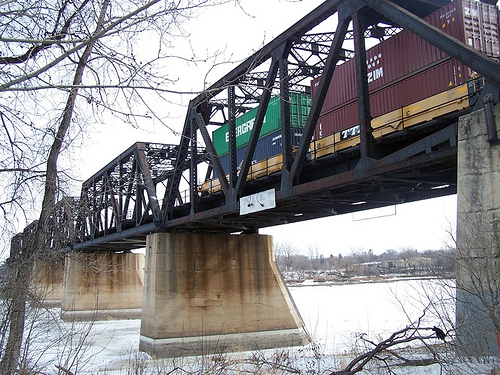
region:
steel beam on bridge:
[92, 181, 112, 248]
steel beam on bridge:
[100, 163, 122, 234]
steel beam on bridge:
[135, 145, 163, 223]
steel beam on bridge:
[160, 111, 190, 208]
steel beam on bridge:
[194, 109, 246, 210]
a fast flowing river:
[8, 286, 497, 356]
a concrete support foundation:
[123, 216, 336, 364]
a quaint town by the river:
[284, 245, 439, 281]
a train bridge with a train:
[11, 26, 484, 216]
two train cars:
[191, 29, 490, 184]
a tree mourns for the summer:
[3, 32, 143, 365]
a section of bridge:
[71, 142, 196, 260]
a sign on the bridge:
[226, 183, 287, 219]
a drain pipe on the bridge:
[471, 86, 497, 142]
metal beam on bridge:
[368, 1, 498, 87]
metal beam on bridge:
[349, 12, 375, 165]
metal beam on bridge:
[288, 22, 348, 173]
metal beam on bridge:
[276, 60, 292, 165]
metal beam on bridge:
[238, 70, 275, 182]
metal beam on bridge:
[227, 83, 237, 189]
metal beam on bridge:
[194, 111, 226, 190]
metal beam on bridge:
[188, 118, 202, 209]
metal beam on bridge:
[160, 118, 192, 221]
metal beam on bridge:
[136, 151, 159, 219]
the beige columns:
[28, 230, 313, 358]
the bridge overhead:
[1, 0, 456, 256]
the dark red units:
[311, 0, 498, 156]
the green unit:
[208, 88, 308, 154]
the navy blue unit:
[212, 124, 300, 177]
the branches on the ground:
[336, 308, 428, 374]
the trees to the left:
[2, 0, 258, 372]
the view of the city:
[273, 238, 466, 283]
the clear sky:
[0, 3, 458, 256]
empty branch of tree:
[209, 94, 244, 123]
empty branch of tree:
[268, 88, 295, 107]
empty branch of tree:
[124, 83, 249, 97]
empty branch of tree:
[0, 198, 17, 228]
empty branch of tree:
[2, 1, 163, 95]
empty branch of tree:
[147, 16, 192, 41]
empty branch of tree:
[39, 76, 151, 130]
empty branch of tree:
[6, 7, 33, 21]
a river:
[14, 289, 485, 371]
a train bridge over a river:
[8, 3, 477, 358]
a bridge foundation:
[116, 213, 336, 357]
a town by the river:
[287, 255, 438, 289]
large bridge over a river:
[0, 0, 498, 359]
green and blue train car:
[207, 85, 312, 185]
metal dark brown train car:
[308, 0, 498, 137]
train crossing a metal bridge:
[198, 0, 498, 203]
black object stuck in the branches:
[430, 323, 446, 340]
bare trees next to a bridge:
[0, 0, 257, 374]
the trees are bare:
[0, 0, 498, 372]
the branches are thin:
[0, 0, 499, 373]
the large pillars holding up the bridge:
[0, 0, 499, 359]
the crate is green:
[212, 92, 311, 155]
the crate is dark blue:
[212, 123, 304, 176]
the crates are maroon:
[310, 0, 498, 139]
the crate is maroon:
[310, 0, 498, 116]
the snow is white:
[0, 258, 497, 373]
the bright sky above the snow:
[0, 0, 498, 374]